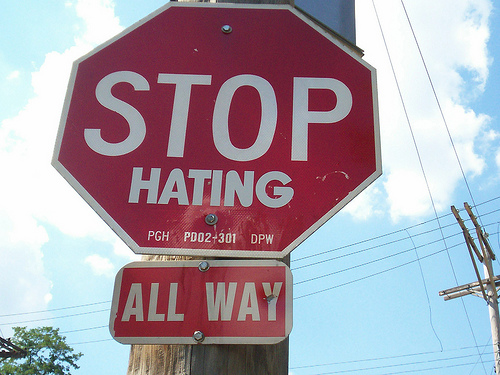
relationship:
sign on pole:
[55, 1, 393, 347] [128, 337, 285, 374]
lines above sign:
[375, 6, 492, 302] [55, 1, 393, 347]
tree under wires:
[1, 325, 81, 373] [1, 294, 116, 353]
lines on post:
[375, 6, 492, 302] [445, 199, 500, 374]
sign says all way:
[111, 263, 301, 349] [124, 278, 285, 321]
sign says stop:
[50, 2, 383, 258] [86, 70, 352, 172]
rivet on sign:
[187, 214, 219, 349] [55, 1, 393, 347]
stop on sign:
[86, 70, 352, 172] [55, 1, 393, 347]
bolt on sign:
[216, 18, 242, 37] [55, 1, 393, 347]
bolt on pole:
[216, 18, 242, 37] [128, 337, 285, 374]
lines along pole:
[375, 6, 492, 302] [128, 337, 285, 374]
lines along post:
[375, 6, 492, 302] [445, 199, 500, 374]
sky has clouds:
[10, 2, 497, 369] [386, 7, 483, 209]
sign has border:
[55, 1, 393, 347] [128, 0, 384, 51]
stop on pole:
[86, 70, 352, 172] [128, 337, 285, 374]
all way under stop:
[124, 278, 285, 321] [86, 70, 352, 172]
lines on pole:
[375, 6, 492, 302] [128, 337, 285, 374]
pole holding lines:
[128, 337, 285, 374] [375, 6, 492, 302]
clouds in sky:
[386, 7, 483, 209] [10, 2, 497, 369]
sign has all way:
[55, 1, 393, 347] [124, 278, 285, 321]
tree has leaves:
[1, 325, 81, 373] [18, 338, 49, 355]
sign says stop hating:
[55, 1, 393, 347] [86, 70, 352, 172]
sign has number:
[55, 1, 393, 347] [148, 230, 283, 250]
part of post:
[221, 168, 258, 201] [445, 199, 500, 374]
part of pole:
[211, 343, 287, 373] [128, 337, 285, 374]